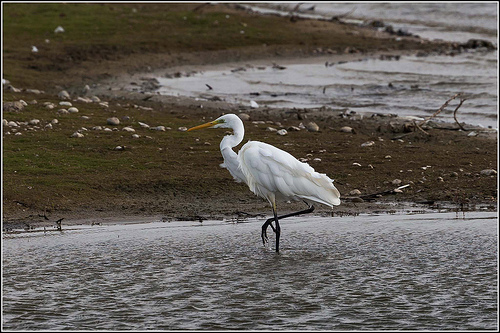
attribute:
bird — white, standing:
[183, 103, 341, 268]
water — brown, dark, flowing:
[228, 282, 268, 305]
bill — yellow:
[190, 115, 212, 133]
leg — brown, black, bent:
[262, 208, 284, 254]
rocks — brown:
[359, 135, 382, 158]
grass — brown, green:
[125, 161, 149, 184]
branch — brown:
[429, 86, 456, 130]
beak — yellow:
[184, 118, 215, 137]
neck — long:
[220, 128, 242, 157]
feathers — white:
[259, 156, 295, 178]